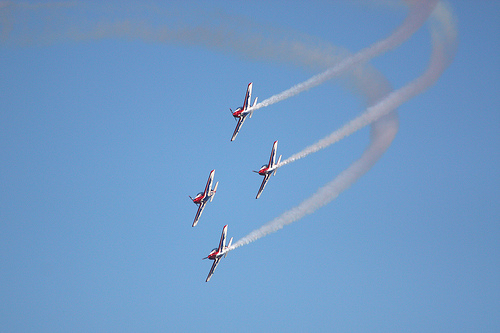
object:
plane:
[253, 140, 281, 200]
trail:
[247, 0, 440, 115]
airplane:
[229, 81, 259, 141]